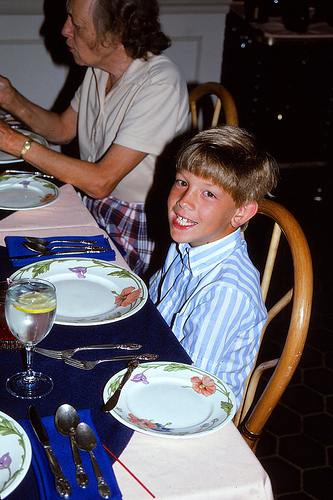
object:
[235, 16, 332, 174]
stove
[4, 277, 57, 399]
glass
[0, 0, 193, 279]
woman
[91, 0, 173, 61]
hair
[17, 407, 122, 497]
napkin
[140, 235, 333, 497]
ground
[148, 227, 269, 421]
shirt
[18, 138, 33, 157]
bracelet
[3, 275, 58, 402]
water glass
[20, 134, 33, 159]
gold watch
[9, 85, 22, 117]
wrist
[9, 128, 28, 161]
wrist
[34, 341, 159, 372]
fork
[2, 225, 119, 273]
white clouds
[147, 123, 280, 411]
boy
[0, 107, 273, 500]
table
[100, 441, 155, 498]
straw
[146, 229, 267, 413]
cloth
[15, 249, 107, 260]
silverwear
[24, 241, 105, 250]
silverwear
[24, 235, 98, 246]
silverwear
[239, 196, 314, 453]
chair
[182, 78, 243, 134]
chair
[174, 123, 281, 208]
hair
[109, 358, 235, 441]
design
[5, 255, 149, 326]
plate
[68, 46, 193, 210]
white shirt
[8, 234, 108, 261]
utensil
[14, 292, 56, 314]
wedge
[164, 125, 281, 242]
head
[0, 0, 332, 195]
background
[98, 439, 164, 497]
stick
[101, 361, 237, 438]
china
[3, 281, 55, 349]
liquid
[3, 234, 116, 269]
napkin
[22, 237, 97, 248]
spoon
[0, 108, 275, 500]
cloth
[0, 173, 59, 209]
plate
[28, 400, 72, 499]
knife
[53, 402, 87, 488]
spoon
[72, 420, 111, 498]
spoon